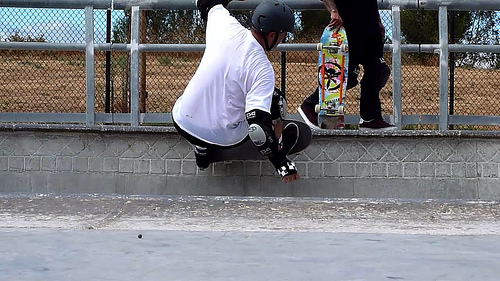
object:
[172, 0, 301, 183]
man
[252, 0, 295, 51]
helmet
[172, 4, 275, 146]
shirt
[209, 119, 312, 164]
skateboard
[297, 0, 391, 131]
person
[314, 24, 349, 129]
skateboard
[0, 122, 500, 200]
wall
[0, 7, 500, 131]
fence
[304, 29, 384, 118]
pants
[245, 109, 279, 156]
elbow pad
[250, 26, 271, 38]
hair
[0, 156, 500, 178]
row of squares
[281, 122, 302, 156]
shoe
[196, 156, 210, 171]
shoe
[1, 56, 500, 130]
field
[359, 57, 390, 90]
kneed pad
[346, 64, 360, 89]
kneed pad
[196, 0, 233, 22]
elbow pad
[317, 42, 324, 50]
wheel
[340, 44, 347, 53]
wheel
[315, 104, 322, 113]
wheel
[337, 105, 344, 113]
wheel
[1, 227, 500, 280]
ground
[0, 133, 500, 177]
design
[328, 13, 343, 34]
hand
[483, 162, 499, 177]
square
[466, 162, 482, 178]
square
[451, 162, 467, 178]
square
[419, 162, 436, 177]
square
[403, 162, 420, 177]
square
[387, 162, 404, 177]
square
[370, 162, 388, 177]
square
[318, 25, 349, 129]
custom art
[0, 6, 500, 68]
sky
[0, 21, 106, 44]
cloudy area